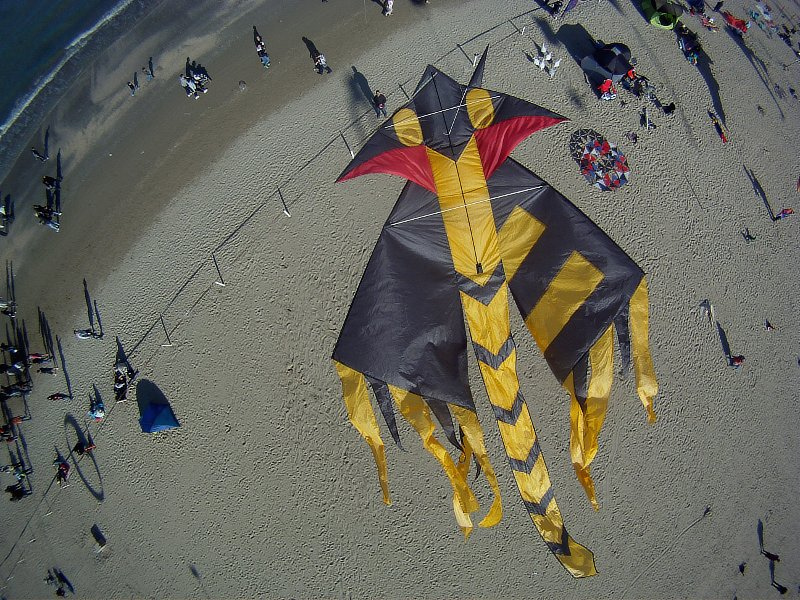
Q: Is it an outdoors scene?
A: Yes, it is outdoors.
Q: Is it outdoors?
A: Yes, it is outdoors.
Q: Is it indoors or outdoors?
A: It is outdoors.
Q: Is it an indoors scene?
A: No, it is outdoors.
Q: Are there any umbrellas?
A: Yes, there is an umbrella.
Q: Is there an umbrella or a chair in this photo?
A: Yes, there is an umbrella.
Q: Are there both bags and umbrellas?
A: No, there is an umbrella but no bags.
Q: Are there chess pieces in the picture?
A: No, there are no chess pieces.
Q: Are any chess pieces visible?
A: No, there are no chess pieces.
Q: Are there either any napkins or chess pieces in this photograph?
A: No, there are no chess pieces or napkins.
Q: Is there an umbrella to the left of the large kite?
A: Yes, there is an umbrella to the left of the kite.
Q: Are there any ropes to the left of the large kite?
A: No, there is an umbrella to the left of the kite.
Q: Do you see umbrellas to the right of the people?
A: Yes, there is an umbrella to the right of the people.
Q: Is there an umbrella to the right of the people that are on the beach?
A: Yes, there is an umbrella to the right of the people.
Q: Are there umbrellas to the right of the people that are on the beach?
A: Yes, there is an umbrella to the right of the people.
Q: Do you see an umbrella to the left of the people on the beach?
A: No, the umbrella is to the right of the people.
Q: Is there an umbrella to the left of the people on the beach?
A: No, the umbrella is to the right of the people.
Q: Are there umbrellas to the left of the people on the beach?
A: No, the umbrella is to the right of the people.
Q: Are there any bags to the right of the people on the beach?
A: No, there is an umbrella to the right of the people.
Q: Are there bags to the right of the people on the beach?
A: No, there is an umbrella to the right of the people.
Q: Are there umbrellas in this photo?
A: Yes, there is an umbrella.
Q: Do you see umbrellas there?
A: Yes, there is an umbrella.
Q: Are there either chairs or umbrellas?
A: Yes, there is an umbrella.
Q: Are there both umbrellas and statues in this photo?
A: No, there is an umbrella but no statues.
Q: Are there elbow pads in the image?
A: No, there are no elbow pads.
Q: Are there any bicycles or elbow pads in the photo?
A: No, there are no elbow pads or bicycles.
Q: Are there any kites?
A: Yes, there is a kite.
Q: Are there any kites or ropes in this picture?
A: Yes, there is a kite.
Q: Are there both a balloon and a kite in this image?
A: No, there is a kite but no balloons.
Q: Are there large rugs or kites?
A: Yes, there is a large kite.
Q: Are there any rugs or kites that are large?
A: Yes, the kite is large.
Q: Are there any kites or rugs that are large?
A: Yes, the kite is large.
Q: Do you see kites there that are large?
A: Yes, there is a large kite.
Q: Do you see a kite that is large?
A: Yes, there is a kite that is large.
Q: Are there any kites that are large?
A: Yes, there is a kite that is large.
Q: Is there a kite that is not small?
A: Yes, there is a large kite.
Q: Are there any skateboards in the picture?
A: No, there are no skateboards.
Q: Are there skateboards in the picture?
A: No, there are no skateboards.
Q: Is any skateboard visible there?
A: No, there are no skateboards.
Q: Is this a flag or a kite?
A: This is a kite.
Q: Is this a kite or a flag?
A: This is a kite.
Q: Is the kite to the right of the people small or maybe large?
A: The kite is large.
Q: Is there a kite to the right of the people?
A: Yes, there is a kite to the right of the people.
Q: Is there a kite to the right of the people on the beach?
A: Yes, there is a kite to the right of the people.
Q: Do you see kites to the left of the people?
A: No, the kite is to the right of the people.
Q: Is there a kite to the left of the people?
A: No, the kite is to the right of the people.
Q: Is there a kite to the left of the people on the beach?
A: No, the kite is to the right of the people.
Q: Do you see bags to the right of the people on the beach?
A: No, there is a kite to the right of the people.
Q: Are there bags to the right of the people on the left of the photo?
A: No, there is a kite to the right of the people.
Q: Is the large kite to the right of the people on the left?
A: Yes, the kite is to the right of the people.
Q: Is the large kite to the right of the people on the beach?
A: Yes, the kite is to the right of the people.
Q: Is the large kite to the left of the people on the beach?
A: No, the kite is to the right of the people.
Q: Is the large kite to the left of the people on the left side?
A: No, the kite is to the right of the people.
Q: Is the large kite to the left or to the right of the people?
A: The kite is to the right of the people.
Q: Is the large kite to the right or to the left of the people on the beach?
A: The kite is to the right of the people.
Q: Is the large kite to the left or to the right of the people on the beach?
A: The kite is to the right of the people.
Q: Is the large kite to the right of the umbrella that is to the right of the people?
A: Yes, the kite is to the right of the umbrella.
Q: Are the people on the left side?
A: Yes, the people are on the left of the image.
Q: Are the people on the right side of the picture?
A: No, the people are on the left of the image.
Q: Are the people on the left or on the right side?
A: The people are on the left of the image.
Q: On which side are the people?
A: The people are on the left of the image.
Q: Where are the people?
A: The people are on the beach.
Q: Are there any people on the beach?
A: Yes, there are people on the beach.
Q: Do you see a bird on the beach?
A: No, there are people on the beach.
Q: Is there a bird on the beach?
A: No, there are people on the beach.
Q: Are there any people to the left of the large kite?
A: Yes, there are people to the left of the kite.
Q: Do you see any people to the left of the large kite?
A: Yes, there are people to the left of the kite.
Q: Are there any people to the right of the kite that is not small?
A: No, the people are to the left of the kite.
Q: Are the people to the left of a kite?
A: Yes, the people are to the left of a kite.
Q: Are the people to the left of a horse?
A: No, the people are to the left of a kite.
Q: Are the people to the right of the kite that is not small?
A: No, the people are to the left of the kite.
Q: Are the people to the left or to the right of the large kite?
A: The people are to the left of the kite.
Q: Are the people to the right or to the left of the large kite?
A: The people are to the left of the kite.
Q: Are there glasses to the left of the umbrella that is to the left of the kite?
A: No, there are people to the left of the umbrella.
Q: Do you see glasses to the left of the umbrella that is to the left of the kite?
A: No, there are people to the left of the umbrella.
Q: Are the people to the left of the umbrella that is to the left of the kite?
A: Yes, the people are to the left of the umbrella.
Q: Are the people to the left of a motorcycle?
A: No, the people are to the left of the umbrella.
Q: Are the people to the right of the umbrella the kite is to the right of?
A: No, the people are to the left of the umbrella.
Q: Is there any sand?
A: Yes, there is sand.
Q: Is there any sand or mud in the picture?
A: Yes, there is sand.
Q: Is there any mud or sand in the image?
A: Yes, there is sand.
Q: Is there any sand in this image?
A: Yes, there is sand.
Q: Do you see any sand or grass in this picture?
A: Yes, there is sand.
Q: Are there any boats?
A: No, there are no boats.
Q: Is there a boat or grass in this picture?
A: No, there are no boats or grass.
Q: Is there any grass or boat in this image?
A: No, there are no boats or grass.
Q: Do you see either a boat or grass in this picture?
A: No, there are no boats or grass.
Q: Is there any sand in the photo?
A: Yes, there is sand.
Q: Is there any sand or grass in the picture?
A: Yes, there is sand.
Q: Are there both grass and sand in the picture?
A: No, there is sand but no grass.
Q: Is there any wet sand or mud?
A: Yes, there is wet sand.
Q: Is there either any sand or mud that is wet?
A: Yes, the sand is wet.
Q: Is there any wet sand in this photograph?
A: Yes, there is wet sand.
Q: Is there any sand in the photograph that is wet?
A: Yes, there is sand that is wet.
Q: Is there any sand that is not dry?
A: Yes, there is wet sand.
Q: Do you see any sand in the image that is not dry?
A: Yes, there is wet sand.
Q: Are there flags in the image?
A: No, there are no flags.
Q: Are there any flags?
A: No, there are no flags.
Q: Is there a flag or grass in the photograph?
A: No, there are no flags or grass.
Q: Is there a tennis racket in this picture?
A: No, there are no rackets.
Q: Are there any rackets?
A: No, there are no rackets.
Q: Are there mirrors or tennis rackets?
A: No, there are no tennis rackets or mirrors.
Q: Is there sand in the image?
A: Yes, there is sand.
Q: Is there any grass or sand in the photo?
A: Yes, there is sand.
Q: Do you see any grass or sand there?
A: Yes, there is sand.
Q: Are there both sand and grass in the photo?
A: No, there is sand but no grass.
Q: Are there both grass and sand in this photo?
A: No, there is sand but no grass.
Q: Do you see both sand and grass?
A: No, there is sand but no grass.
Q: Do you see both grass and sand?
A: No, there is sand but no grass.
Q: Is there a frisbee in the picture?
A: No, there are no frisbees.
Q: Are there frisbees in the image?
A: No, there are no frisbees.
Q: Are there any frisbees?
A: No, there are no frisbees.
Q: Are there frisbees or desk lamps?
A: No, there are no frisbees or desk lamps.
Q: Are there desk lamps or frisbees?
A: No, there are no frisbees or desk lamps.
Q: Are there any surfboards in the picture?
A: No, there are no surfboards.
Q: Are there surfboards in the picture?
A: No, there are no surfboards.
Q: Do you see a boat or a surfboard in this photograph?
A: No, there are no surfboards or boats.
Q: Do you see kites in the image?
A: Yes, there is a kite.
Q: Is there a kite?
A: Yes, there is a kite.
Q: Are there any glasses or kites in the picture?
A: Yes, there is a kite.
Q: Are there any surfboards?
A: No, there are no surfboards.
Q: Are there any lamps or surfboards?
A: No, there are no surfboards or lamps.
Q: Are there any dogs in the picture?
A: No, there are no dogs.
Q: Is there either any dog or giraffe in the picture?
A: No, there are no dogs or giraffes.